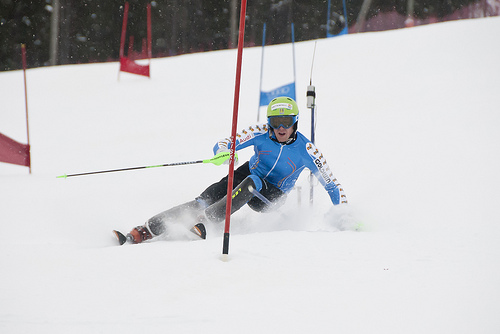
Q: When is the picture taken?
A: Daytime.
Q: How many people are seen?
A: One.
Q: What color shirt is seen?
A: Blue.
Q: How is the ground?
A: Covered with snow.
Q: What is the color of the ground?
A: White.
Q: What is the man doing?
A: Skating.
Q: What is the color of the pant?
A: Black.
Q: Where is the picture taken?
A: At a ski slope.